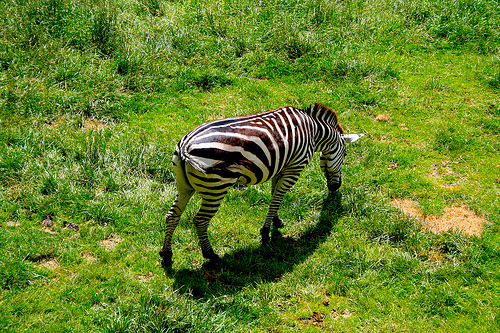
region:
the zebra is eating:
[307, 123, 364, 236]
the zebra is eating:
[314, 96, 371, 198]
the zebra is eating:
[315, 97, 366, 212]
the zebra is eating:
[314, 123, 368, 194]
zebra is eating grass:
[312, 132, 357, 208]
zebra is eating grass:
[301, 115, 365, 223]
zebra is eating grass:
[305, 120, 362, 222]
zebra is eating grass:
[307, 109, 367, 217]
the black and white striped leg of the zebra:
[157, 156, 191, 264]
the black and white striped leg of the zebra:
[186, 156, 226, 261]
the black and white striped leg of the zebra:
[260, 150, 300, 245]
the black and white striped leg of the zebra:
[268, 162, 283, 232]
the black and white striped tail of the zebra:
[177, 135, 209, 175]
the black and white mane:
[303, 100, 343, 131]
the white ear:
[343, 132, 370, 147]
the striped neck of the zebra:
[309, 114, 336, 154]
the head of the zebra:
[321, 135, 346, 187]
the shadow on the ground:
[172, 199, 345, 301]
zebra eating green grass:
[144, 97, 361, 286]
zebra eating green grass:
[119, 71, 376, 313]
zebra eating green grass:
[118, 90, 370, 321]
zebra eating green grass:
[111, 96, 355, 306]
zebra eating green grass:
[131, 86, 378, 311]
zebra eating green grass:
[118, 79, 375, 326]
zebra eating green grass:
[104, 73, 369, 322]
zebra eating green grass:
[106, 75, 406, 291]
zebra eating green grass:
[119, 68, 381, 305]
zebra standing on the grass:
[127, 89, 380, 288]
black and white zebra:
[151, 78, 382, 273]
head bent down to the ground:
[316, 107, 354, 207]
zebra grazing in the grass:
[129, 95, 398, 280]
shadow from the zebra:
[168, 188, 349, 306]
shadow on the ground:
[169, 190, 357, 304]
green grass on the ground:
[0, 0, 492, 332]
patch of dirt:
[380, 183, 491, 245]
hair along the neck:
[297, 96, 354, 135]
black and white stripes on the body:
[152, 83, 370, 271]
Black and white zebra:
[160, 103, 363, 266]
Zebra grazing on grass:
[160, 101, 365, 266]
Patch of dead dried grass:
[388, 193, 493, 241]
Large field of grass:
[0, 0, 498, 330]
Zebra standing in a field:
[160, 103, 365, 264]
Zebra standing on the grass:
[157, 103, 365, 268]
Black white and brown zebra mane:
[305, 102, 345, 132]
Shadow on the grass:
[160, 190, 345, 307]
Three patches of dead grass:
[22, 233, 125, 280]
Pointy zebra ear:
[340, 130, 365, 146]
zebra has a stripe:
[191, 136, 271, 166]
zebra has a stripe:
[205, 168, 251, 188]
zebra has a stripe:
[188, 171, 220, 181]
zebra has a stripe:
[200, 189, 227, 195]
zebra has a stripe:
[202, 196, 222, 200]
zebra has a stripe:
[187, 134, 272, 168]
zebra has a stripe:
[194, 126, 276, 178]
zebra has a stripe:
[245, 121, 285, 172]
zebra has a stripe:
[274, 111, 286, 132]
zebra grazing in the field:
[153, 83, 355, 260]